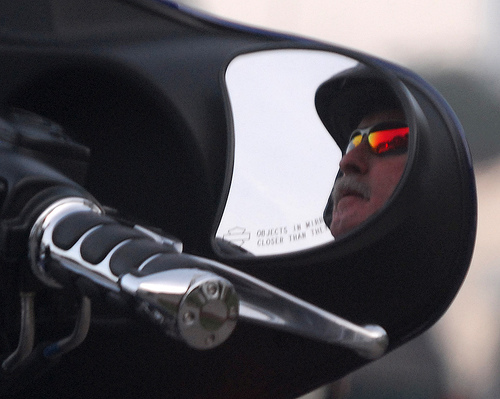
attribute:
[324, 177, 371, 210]
mustache — gray 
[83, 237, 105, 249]
black — chrome 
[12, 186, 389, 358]
bike handle — black 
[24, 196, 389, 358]
handlebar — metal 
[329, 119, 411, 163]
sunglasses — red 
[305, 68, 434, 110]
helmet — black 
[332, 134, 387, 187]
nose — man's